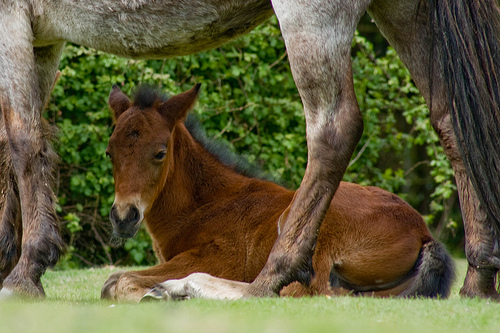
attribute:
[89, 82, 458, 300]
horse — brown, baby 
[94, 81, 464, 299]
colt — laying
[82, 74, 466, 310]
horse — baby 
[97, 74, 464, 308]
foal — brown 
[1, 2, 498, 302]
mother — dappled 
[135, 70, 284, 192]
mane — black 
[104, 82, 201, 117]
ears — brown 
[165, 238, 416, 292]
hind leg — white  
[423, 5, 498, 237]
tail — long , black 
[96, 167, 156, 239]
muzzle — white , ring 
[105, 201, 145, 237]
nose — black 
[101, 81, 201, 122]
ears — standing up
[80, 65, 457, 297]
horse — baby 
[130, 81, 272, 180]
mane — black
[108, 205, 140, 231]
nose — black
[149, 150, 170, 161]
eye — dark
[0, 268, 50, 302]
hoof — brown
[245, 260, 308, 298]
hoof — brown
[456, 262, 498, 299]
hoof — brown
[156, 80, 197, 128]
ear — brown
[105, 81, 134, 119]
ear — brown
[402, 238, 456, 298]
tail — black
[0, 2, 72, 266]
leg — brown, black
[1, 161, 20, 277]
leg — brown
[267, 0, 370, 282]
leg — brown, black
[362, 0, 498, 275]
leg — brown, black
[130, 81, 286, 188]
hair — black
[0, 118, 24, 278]
leg — black